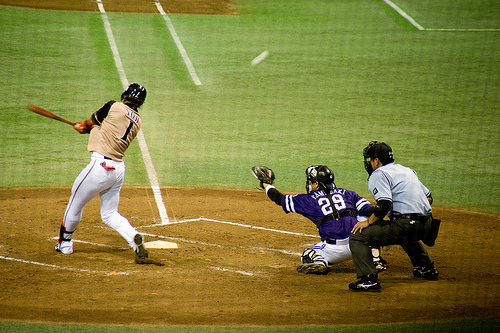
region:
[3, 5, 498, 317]
a scene of baseball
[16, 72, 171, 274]
a batter swinging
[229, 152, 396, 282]
a catcher holding out his glove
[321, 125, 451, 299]
an umpire crouching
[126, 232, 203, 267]
a white home plate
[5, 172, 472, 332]
a brown patch of dirt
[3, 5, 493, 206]
a green grass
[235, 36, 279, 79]
a white baseball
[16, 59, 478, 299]
three baseball players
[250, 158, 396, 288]
a purple catcher with 29 on the uniform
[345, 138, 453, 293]
the umpire is crouching down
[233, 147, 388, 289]
the catcher is on his knees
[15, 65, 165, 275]
the batter just swung the bat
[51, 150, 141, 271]
the batter's pants are white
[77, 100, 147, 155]
the batter's shirt is tan and black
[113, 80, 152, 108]
the batter is wearing a black helmet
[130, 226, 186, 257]
home plate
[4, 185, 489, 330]
the dirt is brown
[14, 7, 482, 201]
the field is grassy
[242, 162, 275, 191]
the catcher's mitt is black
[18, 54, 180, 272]
batter standing in the batter's box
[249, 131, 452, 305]
umpire hunched over behind the catcher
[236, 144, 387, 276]
catcher with his arm stretched out to catch the ball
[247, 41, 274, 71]
tiny white baseball that is in motion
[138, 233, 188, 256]
tan home plate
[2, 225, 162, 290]
white lines indicating the batter's box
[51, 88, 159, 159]
tan shirt with black sleeves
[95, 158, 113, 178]
red batting gloves in the back pocket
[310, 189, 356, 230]
white writing on the back of the jersey indicating name and number of player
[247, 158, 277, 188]
brown catcher's mit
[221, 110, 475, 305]
the catcher and the umpire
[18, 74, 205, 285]
the batter just swung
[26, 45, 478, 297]
the sport is baseball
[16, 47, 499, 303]
they are at home plate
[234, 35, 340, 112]
the ball is out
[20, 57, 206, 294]
the jersey is tan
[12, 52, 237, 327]
the batter has a helmet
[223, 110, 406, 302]
the jersey is purple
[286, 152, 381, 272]
catcher is number 29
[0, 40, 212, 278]
batter is number one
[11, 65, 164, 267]
baseball player swinging his bat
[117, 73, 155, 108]
man wearing a black baseball cap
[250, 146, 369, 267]
catcher wearing a purple shirt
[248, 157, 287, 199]
a catcher's glove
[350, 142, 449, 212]
umpire wearing a white shirt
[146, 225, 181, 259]
a white plate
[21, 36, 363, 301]
two baseball players from different teams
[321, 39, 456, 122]
the green grass of a baseball field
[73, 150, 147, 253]
baseball player wearing white pants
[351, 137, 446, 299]
umpire crouching down